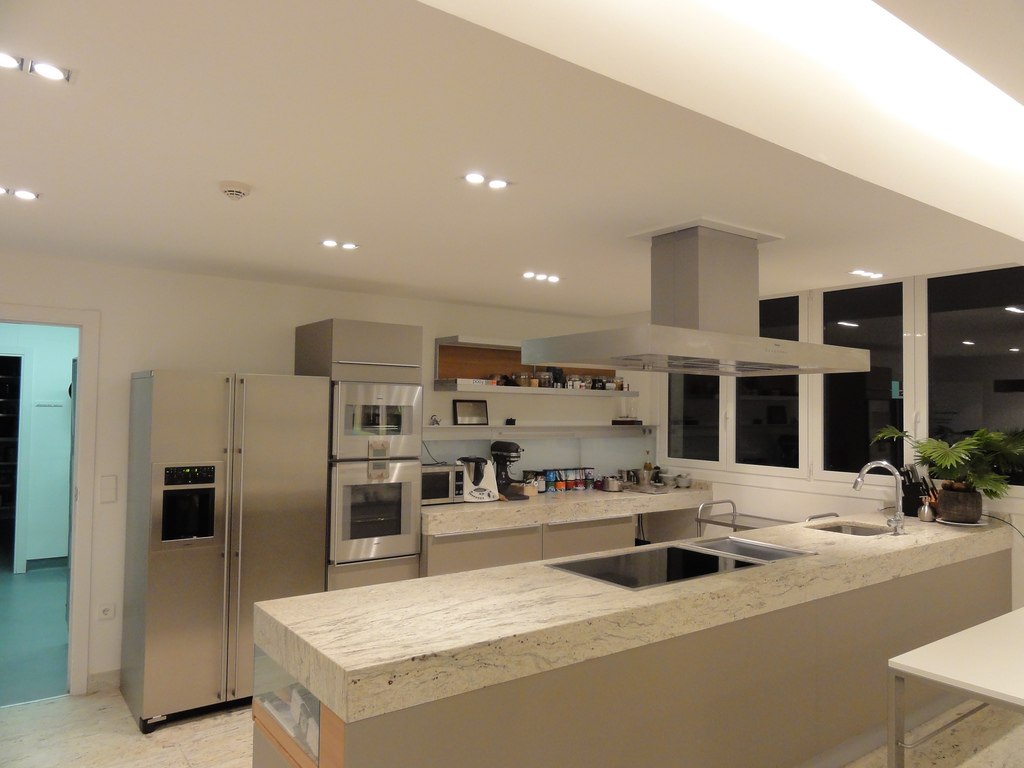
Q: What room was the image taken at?
A: It was taken at the kitchen.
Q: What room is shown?
A: It is a kitchen.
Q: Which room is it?
A: It is a kitchen.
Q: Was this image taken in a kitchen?
A: Yes, it was taken in a kitchen.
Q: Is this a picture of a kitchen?
A: Yes, it is showing a kitchen.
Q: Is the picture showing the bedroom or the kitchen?
A: It is showing the kitchen.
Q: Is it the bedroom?
A: No, it is the kitchen.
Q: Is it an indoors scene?
A: Yes, it is indoors.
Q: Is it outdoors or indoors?
A: It is indoors.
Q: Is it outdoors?
A: No, it is indoors.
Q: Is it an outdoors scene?
A: No, it is indoors.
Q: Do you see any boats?
A: No, there are no boats.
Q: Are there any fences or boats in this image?
A: No, there are no boats or fences.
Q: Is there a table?
A: Yes, there is a table.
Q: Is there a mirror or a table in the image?
A: Yes, there is a table.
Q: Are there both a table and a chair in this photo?
A: No, there is a table but no chairs.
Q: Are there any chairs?
A: No, there are no chairs.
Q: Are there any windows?
A: Yes, there is a window.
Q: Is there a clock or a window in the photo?
A: Yes, there is a window.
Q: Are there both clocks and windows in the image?
A: No, there is a window but no clocks.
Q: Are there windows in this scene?
A: Yes, there is a window.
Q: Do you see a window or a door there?
A: Yes, there is a window.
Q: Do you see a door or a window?
A: Yes, there is a window.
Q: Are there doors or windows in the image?
A: Yes, there is a window.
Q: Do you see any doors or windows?
A: Yes, there is a window.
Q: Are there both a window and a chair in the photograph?
A: No, there is a window but no chairs.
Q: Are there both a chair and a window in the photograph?
A: No, there is a window but no chairs.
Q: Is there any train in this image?
A: No, there are no trains.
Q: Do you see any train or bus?
A: No, there are no trains or buses.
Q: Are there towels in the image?
A: No, there are no towels.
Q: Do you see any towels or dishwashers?
A: No, there are no towels or dishwashers.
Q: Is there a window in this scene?
A: Yes, there is a window.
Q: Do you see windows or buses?
A: Yes, there is a window.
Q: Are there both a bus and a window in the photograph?
A: No, there is a window but no buses.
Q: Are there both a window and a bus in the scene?
A: No, there is a window but no buses.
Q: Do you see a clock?
A: No, there are no clocks.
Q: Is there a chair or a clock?
A: No, there are no clocks or chairs.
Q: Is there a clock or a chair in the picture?
A: No, there are no clocks or chairs.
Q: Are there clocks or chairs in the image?
A: No, there are no clocks or chairs.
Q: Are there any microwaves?
A: Yes, there is a microwave.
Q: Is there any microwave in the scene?
A: Yes, there is a microwave.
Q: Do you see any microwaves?
A: Yes, there is a microwave.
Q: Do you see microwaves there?
A: Yes, there is a microwave.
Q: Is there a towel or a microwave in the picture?
A: Yes, there is a microwave.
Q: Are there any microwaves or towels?
A: Yes, there is a microwave.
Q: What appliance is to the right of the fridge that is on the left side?
A: The appliance is a microwave.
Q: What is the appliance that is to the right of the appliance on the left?
A: The appliance is a microwave.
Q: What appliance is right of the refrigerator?
A: The appliance is a microwave.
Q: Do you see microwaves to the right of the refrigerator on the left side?
A: Yes, there is a microwave to the right of the refrigerator.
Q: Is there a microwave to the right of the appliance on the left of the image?
A: Yes, there is a microwave to the right of the refrigerator.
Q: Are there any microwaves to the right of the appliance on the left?
A: Yes, there is a microwave to the right of the refrigerator.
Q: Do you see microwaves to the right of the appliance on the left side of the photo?
A: Yes, there is a microwave to the right of the refrigerator.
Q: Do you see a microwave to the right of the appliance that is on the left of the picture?
A: Yes, there is a microwave to the right of the refrigerator.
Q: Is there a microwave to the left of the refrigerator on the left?
A: No, the microwave is to the right of the freezer.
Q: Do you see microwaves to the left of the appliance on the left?
A: No, the microwave is to the right of the freezer.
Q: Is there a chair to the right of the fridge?
A: No, there is a microwave to the right of the fridge.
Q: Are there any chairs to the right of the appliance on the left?
A: No, there is a microwave to the right of the fridge.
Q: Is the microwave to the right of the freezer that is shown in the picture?
A: Yes, the microwave is to the right of the freezer.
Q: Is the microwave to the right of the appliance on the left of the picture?
A: Yes, the microwave is to the right of the freezer.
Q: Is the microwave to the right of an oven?
A: No, the microwave is to the right of the freezer.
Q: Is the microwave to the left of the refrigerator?
A: No, the microwave is to the right of the refrigerator.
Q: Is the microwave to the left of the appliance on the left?
A: No, the microwave is to the right of the refrigerator.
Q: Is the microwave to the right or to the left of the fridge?
A: The microwave is to the right of the fridge.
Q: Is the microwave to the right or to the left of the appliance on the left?
A: The microwave is to the right of the fridge.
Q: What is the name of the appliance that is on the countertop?
A: The appliance is a microwave.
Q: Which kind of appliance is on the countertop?
A: The appliance is a microwave.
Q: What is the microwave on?
A: The microwave is on the countertop.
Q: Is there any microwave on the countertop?
A: Yes, there is a microwave on the countertop.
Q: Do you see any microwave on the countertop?
A: Yes, there is a microwave on the countertop.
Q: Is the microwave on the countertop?
A: Yes, the microwave is on the countertop.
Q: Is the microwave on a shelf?
A: No, the microwave is on the countertop.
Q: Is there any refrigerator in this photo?
A: Yes, there is a refrigerator.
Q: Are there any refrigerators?
A: Yes, there is a refrigerator.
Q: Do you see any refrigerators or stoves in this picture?
A: Yes, there is a refrigerator.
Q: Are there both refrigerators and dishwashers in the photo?
A: No, there is a refrigerator but no dishwashers.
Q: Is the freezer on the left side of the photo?
A: Yes, the freezer is on the left of the image.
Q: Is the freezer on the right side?
A: No, the freezer is on the left of the image.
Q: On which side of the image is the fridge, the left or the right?
A: The fridge is on the left of the image.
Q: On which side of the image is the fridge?
A: The fridge is on the left of the image.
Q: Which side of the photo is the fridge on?
A: The fridge is on the left of the image.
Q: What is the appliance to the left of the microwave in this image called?
A: The appliance is a refrigerator.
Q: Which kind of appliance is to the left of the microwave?
A: The appliance is a refrigerator.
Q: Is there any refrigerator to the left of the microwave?
A: Yes, there is a refrigerator to the left of the microwave.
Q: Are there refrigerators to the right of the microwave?
A: No, the refrigerator is to the left of the microwave.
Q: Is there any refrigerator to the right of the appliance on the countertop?
A: No, the refrigerator is to the left of the microwave.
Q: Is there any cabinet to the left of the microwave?
A: No, there is a refrigerator to the left of the microwave.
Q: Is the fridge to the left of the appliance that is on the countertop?
A: Yes, the fridge is to the left of the microwave.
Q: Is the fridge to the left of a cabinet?
A: No, the fridge is to the left of the microwave.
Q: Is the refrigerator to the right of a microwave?
A: No, the refrigerator is to the left of a microwave.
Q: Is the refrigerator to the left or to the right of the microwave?
A: The refrigerator is to the left of the microwave.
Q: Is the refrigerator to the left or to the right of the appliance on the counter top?
A: The refrigerator is to the left of the microwave.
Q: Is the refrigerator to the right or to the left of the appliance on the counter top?
A: The refrigerator is to the left of the microwave.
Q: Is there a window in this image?
A: Yes, there is a window.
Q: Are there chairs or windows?
A: Yes, there is a window.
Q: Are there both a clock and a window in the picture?
A: No, there is a window but no clocks.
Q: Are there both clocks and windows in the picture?
A: No, there is a window but no clocks.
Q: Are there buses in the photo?
A: No, there are no buses.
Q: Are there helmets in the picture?
A: No, there are no helmets.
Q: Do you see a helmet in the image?
A: No, there are no helmets.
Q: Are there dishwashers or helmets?
A: No, there are no helmets or dishwashers.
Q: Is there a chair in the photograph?
A: No, there are no chairs.